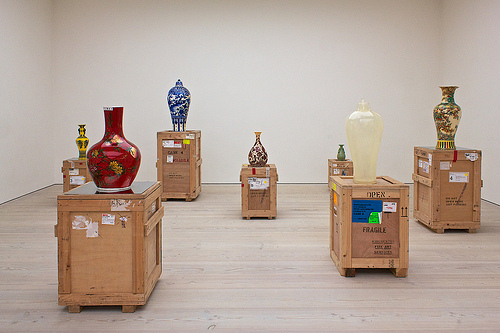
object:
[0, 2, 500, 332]
room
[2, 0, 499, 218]
walls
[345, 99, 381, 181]
vase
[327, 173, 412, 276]
crate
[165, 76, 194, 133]
vase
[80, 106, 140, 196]
vase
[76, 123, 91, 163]
vase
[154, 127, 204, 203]
crate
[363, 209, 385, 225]
label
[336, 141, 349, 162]
vase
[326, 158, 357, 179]
crate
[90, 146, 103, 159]
flower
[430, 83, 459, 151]
vase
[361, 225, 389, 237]
fragile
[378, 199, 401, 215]
label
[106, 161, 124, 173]
flower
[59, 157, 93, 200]
crate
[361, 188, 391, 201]
writing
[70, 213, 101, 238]
labels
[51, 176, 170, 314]
crate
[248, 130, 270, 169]
vase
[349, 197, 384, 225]
label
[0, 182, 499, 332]
floor